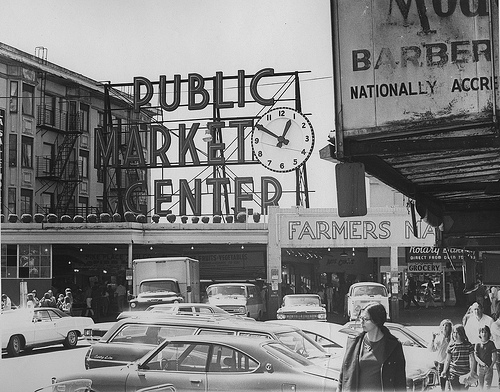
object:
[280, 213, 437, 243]
sign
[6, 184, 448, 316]
market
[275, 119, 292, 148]
black hands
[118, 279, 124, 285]
head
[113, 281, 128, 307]
person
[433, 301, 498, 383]
children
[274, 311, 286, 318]
headlights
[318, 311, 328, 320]
headlights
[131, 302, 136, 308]
headlights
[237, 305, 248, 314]
headlights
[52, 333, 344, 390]
car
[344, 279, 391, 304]
car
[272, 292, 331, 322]
car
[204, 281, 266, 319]
car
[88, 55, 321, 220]
sign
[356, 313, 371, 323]
glasses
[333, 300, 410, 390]
woman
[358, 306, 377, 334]
face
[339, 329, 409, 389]
coat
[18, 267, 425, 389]
station wagon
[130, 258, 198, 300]
truck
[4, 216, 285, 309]
market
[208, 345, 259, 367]
window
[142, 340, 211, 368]
window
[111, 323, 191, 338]
window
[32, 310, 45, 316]
window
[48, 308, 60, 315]
window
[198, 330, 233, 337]
window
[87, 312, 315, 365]
car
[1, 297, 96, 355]
car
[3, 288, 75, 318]
people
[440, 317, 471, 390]
girl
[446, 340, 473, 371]
shirt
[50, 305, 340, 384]
cars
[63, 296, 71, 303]
head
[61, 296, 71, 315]
person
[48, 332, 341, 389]
vehicle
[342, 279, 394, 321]
vehicle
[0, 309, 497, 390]
road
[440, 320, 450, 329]
person's head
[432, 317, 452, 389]
child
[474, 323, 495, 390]
child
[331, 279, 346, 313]
person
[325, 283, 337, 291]
head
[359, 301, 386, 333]
head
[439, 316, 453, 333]
head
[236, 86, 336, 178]
clock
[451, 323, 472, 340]
head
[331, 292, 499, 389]
people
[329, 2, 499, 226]
market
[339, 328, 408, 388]
jacket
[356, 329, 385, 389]
shirt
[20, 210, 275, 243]
roof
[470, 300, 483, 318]
head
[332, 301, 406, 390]
person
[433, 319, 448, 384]
person